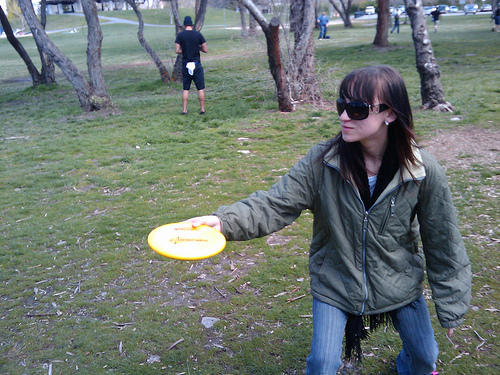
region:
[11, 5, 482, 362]
people in a public park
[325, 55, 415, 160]
woman in sunglasses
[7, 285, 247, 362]
ground with patchy grass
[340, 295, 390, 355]
black scarf hanging down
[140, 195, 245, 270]
yellow frisbee in hand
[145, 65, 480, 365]
young woman gets ready to throw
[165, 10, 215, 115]
young man with his back turned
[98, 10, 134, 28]
paved paths in the park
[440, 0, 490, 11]
cars in a parking lot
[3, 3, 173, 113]
trees with thin trunks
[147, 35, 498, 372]
young woman in park tossing frisbee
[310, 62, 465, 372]
woman wearing grey coat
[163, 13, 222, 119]
man wearing black beanie hat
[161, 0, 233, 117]
man wearing black shirt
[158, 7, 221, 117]
man wearing black shorts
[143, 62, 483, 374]
woman with brown hair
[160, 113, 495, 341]
grey coat with two zippers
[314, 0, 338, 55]
man wearing blue coat in background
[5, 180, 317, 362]
twigs scattered on ground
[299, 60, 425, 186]
woman wearing small silver earrings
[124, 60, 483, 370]
a woman about to throw a frisbee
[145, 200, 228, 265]
a yellow frisbee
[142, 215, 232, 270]
a hand holding a frisbee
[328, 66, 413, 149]
the head of a woman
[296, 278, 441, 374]
the legs of a woman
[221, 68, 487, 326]
a woman wearing a green jacket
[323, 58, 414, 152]
a woman wearing sunglasses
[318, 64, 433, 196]
a woman with black hair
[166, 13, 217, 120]
the backside of a man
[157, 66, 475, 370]
a dark haired woman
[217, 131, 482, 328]
a green jacket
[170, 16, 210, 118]
a man wearing dark clothing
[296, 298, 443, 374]
a pair of blue jeans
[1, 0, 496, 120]
a grove of trees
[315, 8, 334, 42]
a person dressed all in blue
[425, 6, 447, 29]
a person wearing a black top and light pants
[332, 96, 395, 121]
a pair of sunglasses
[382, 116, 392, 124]
a small white earring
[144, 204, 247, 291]
a yellow frisbee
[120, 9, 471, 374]
they are in a park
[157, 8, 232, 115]
his arms are bent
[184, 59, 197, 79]
this is a white towel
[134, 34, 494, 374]
she is holding the frisbee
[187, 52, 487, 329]
she is wearing a green jacket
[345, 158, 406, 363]
she is wearing a black scarf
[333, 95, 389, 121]
a large pair of sunglasses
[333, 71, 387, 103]
these are her bangs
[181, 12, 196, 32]
he has a black beanie on his head